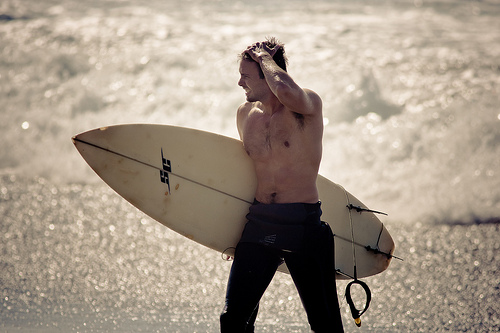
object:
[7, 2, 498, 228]
background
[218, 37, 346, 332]
man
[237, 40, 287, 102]
head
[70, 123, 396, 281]
surfboard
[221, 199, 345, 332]
wetsuit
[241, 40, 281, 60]
hand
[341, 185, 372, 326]
rope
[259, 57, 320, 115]
arm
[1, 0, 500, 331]
ocean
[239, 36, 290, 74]
hair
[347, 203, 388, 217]
fin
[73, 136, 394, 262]
line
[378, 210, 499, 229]
wave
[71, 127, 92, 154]
point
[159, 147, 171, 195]
logo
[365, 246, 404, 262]
fin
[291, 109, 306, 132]
hair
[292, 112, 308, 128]
armpit